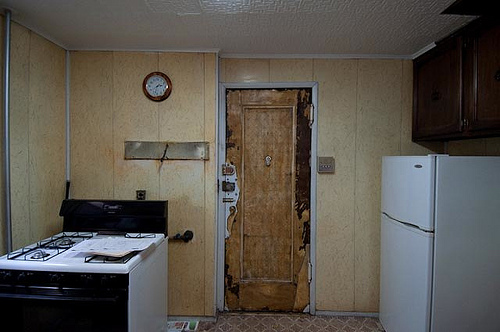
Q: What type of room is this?
A: It is a kitchen.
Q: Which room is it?
A: It is a kitchen.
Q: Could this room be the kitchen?
A: Yes, it is the kitchen.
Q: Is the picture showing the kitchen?
A: Yes, it is showing the kitchen.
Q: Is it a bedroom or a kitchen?
A: It is a kitchen.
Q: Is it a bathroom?
A: No, it is a kitchen.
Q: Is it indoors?
A: Yes, it is indoors.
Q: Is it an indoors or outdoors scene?
A: It is indoors.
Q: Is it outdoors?
A: No, it is indoors.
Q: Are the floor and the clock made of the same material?
A: No, the floor is made of plastic and the clock is made of wood.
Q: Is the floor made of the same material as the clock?
A: No, the floor is made of plastic and the clock is made of wood.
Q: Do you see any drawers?
A: No, there are no drawers.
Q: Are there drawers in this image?
A: No, there are no drawers.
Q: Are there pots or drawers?
A: No, there are no drawers or pots.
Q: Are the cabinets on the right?
A: Yes, the cabinets are on the right of the image.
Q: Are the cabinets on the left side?
A: No, the cabinets are on the right of the image.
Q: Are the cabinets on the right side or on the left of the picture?
A: The cabinets are on the right of the image.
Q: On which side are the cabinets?
A: The cabinets are on the right of the image.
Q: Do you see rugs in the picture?
A: No, there are no rugs.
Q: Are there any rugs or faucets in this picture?
A: No, there are no rugs or faucets.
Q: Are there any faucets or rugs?
A: No, there are no rugs or faucets.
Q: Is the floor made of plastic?
A: Yes, the floor is made of plastic.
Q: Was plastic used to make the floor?
A: Yes, the floor is made of plastic.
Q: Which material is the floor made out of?
A: The floor is made of plastic.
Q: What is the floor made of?
A: The floor is made of plastic.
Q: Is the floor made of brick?
A: No, the floor is made of plastic.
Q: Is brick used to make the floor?
A: No, the floor is made of plastic.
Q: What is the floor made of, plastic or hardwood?
A: The floor is made of plastic.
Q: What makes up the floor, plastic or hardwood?
A: The floor is made of plastic.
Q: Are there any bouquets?
A: No, there are no bouquets.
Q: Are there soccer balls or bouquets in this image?
A: No, there are no bouquets or soccer balls.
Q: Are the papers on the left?
A: Yes, the papers are on the left of the image.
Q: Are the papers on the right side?
A: No, the papers are on the left of the image.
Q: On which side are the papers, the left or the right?
A: The papers are on the left of the image.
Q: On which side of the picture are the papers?
A: The papers are on the left of the image.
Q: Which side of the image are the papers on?
A: The papers are on the left of the image.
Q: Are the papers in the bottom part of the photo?
A: Yes, the papers are in the bottom of the image.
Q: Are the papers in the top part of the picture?
A: No, the papers are in the bottom of the image.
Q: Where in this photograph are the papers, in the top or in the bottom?
A: The papers are in the bottom of the image.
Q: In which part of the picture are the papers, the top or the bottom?
A: The papers are in the bottom of the image.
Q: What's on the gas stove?
A: The papers are on the gas stove.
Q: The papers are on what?
A: The papers are on the gas stove.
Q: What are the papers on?
A: The papers are on the gas stove.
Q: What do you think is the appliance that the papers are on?
A: The appliance is a gas stove.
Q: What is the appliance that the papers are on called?
A: The appliance is a gas stove.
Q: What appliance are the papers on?
A: The papers are on the gas stove.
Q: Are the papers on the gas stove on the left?
A: Yes, the papers are on the gas stove.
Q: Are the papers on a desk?
A: No, the papers are on the gas stove.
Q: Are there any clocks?
A: Yes, there is a clock.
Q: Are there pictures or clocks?
A: Yes, there is a clock.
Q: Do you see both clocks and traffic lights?
A: No, there is a clock but no traffic lights.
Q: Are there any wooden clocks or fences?
A: Yes, there is a wood clock.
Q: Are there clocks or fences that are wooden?
A: Yes, the clock is wooden.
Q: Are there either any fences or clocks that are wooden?
A: Yes, the clock is wooden.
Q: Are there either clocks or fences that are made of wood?
A: Yes, the clock is made of wood.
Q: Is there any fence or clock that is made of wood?
A: Yes, the clock is made of wood.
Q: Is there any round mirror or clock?
A: Yes, there is a round clock.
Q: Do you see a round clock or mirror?
A: Yes, there is a round clock.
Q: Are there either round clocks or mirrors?
A: Yes, there is a round clock.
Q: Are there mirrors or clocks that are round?
A: Yes, the clock is round.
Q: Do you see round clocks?
A: Yes, there is a round clock.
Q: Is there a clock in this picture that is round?
A: Yes, there is a clock that is round.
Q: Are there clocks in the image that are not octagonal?
A: Yes, there is an round clock.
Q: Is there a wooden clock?
A: Yes, there is a wood clock.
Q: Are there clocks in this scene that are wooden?
A: Yes, there is a clock that is wooden.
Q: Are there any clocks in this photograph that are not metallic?
A: Yes, there is a wooden clock.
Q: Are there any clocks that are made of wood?
A: Yes, there is a clock that is made of wood.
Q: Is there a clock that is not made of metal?
A: Yes, there is a clock that is made of wood.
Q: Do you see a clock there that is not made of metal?
A: Yes, there is a clock that is made of wood.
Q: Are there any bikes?
A: No, there are no bikes.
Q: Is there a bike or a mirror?
A: No, there are no bikes or mirrors.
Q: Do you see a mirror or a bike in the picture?
A: No, there are no bikes or mirrors.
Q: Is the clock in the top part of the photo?
A: Yes, the clock is in the top of the image.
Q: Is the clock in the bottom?
A: No, the clock is in the top of the image.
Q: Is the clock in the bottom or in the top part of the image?
A: The clock is in the top of the image.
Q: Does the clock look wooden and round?
A: Yes, the clock is wooden and round.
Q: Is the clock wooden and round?
A: Yes, the clock is wooden and round.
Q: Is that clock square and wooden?
A: No, the clock is wooden but round.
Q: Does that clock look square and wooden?
A: No, the clock is wooden but round.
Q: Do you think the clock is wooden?
A: Yes, the clock is wooden.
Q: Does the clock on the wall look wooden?
A: Yes, the clock is wooden.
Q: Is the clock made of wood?
A: Yes, the clock is made of wood.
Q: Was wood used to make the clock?
A: Yes, the clock is made of wood.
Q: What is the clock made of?
A: The clock is made of wood.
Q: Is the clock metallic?
A: No, the clock is wooden.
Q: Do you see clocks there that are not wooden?
A: No, there is a clock but it is wooden.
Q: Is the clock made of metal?
A: No, the clock is made of wood.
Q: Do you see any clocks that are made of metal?
A: No, there is a clock but it is made of wood.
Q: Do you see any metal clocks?
A: No, there is a clock but it is made of wood.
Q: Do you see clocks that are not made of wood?
A: No, there is a clock but it is made of wood.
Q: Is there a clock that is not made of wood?
A: No, there is a clock but it is made of wood.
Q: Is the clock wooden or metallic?
A: The clock is wooden.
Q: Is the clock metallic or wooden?
A: The clock is wooden.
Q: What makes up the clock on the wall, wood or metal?
A: The clock is made of wood.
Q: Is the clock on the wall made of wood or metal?
A: The clock is made of wood.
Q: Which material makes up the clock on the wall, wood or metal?
A: The clock is made of wood.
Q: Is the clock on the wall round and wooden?
A: Yes, the clock is round and wooden.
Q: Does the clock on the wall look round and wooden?
A: Yes, the clock is round and wooden.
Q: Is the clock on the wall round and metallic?
A: No, the clock is round but wooden.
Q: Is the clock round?
A: Yes, the clock is round.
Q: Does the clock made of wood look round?
A: Yes, the clock is round.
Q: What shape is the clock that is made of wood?
A: The clock is round.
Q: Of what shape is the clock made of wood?
A: The clock is round.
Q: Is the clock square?
A: No, the clock is round.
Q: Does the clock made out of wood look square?
A: No, the clock is round.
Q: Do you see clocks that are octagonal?
A: No, there is a clock but it is round.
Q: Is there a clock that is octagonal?
A: No, there is a clock but it is round.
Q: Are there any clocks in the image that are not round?
A: No, there is a clock but it is round.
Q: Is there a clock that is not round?
A: No, there is a clock but it is round.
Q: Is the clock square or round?
A: The clock is round.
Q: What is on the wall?
A: The clock is on the wall.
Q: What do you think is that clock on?
A: The clock is on the wall.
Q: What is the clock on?
A: The clock is on the wall.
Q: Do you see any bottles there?
A: No, there are no bottles.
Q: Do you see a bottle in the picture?
A: No, there are no bottles.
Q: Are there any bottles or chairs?
A: No, there are no bottles or chairs.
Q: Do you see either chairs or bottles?
A: No, there are no bottles or chairs.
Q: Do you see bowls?
A: No, there are no bowls.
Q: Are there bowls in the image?
A: No, there are no bowls.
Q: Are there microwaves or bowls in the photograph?
A: No, there are no bowls or microwaves.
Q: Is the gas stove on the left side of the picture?
A: Yes, the gas stove is on the left of the image.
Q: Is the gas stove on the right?
A: No, the gas stove is on the left of the image.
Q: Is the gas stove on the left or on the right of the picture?
A: The gas stove is on the left of the image.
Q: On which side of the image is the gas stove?
A: The gas stove is on the left of the image.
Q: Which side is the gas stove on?
A: The gas stove is on the left of the image.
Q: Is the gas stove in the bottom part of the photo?
A: Yes, the gas stove is in the bottom of the image.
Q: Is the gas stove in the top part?
A: No, the gas stove is in the bottom of the image.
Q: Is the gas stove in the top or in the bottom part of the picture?
A: The gas stove is in the bottom of the image.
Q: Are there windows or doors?
A: Yes, there is a door.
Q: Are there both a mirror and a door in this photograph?
A: No, there is a door but no mirrors.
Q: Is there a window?
A: No, there are no windows.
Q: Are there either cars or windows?
A: No, there are no windows or cars.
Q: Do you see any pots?
A: No, there are no pots.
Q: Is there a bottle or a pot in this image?
A: No, there are no pots or bottles.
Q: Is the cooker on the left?
A: Yes, the cooker is on the left of the image.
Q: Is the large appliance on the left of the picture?
A: Yes, the cooker is on the left of the image.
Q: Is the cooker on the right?
A: No, the cooker is on the left of the image.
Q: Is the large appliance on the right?
A: No, the cooker is on the left of the image.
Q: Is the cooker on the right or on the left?
A: The cooker is on the left of the image.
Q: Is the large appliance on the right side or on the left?
A: The cooker is on the left of the image.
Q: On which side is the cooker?
A: The cooker is on the left of the image.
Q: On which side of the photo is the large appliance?
A: The cooker is on the left of the image.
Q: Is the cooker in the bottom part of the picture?
A: Yes, the cooker is in the bottom of the image.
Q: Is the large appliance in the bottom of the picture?
A: Yes, the cooker is in the bottom of the image.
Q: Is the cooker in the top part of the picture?
A: No, the cooker is in the bottom of the image.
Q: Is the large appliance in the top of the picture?
A: No, the cooker is in the bottom of the image.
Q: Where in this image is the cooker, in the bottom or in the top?
A: The cooker is in the bottom of the image.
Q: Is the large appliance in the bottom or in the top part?
A: The cooker is in the bottom of the image.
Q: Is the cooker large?
A: Yes, the cooker is large.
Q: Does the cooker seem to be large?
A: Yes, the cooker is large.